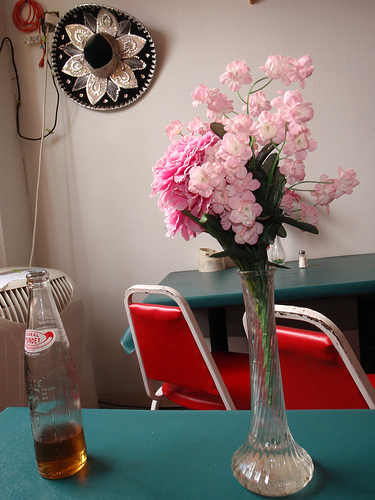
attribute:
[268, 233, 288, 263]
glass — here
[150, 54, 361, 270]
flowers — pink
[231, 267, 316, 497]
vase — glass, here, clear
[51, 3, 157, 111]
hat — mexican, black, white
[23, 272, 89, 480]
bottle — half empty, glass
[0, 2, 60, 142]
electrical wire — black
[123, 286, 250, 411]
chair — old, red, white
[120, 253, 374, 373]
table — blue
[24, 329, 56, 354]
label — red, white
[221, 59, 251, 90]
flower — here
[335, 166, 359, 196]
flower — here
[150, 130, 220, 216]
flower — here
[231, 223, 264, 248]
flower — here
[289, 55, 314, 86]
flower — here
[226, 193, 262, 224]
flower — here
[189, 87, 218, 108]
flower — here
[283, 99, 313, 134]
flower — here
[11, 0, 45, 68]
cord — orange